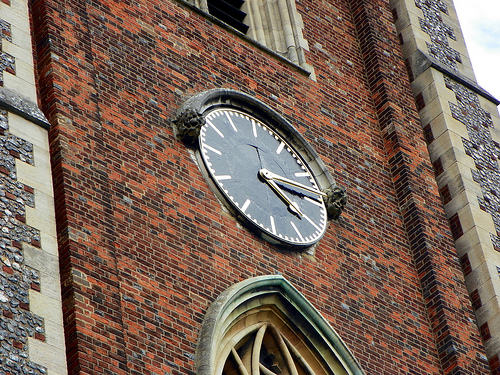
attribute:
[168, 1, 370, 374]
windows — designed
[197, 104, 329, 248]
clock — black, gold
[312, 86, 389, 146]
brick — grey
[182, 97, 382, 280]
clock — black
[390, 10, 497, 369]
pillar — gray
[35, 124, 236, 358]
bricks — in the picture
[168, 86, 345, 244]
clock — in the picture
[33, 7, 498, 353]
building — black and red, brick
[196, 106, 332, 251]
dashes — gold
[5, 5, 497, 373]
bricks — red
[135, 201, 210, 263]
bricks — red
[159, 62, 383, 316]
clock — in the picture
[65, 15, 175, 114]
wall — brick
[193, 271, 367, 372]
archway — stone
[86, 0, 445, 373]
wall — brick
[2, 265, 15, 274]
bricks — small, red